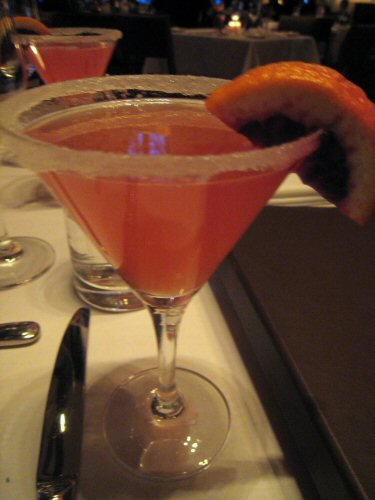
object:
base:
[102, 365, 233, 480]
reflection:
[58, 411, 66, 433]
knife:
[33, 305, 91, 499]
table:
[0, 160, 375, 499]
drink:
[12, 25, 122, 88]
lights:
[222, 12, 243, 35]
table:
[171, 27, 321, 90]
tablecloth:
[170, 25, 324, 81]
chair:
[144, 56, 169, 76]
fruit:
[206, 62, 375, 227]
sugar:
[39, 146, 174, 178]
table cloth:
[1, 158, 351, 500]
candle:
[228, 13, 243, 28]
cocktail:
[29, 99, 294, 297]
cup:
[2, 68, 333, 482]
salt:
[0, 134, 323, 185]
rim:
[2, 71, 327, 190]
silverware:
[32, 305, 91, 500]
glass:
[18, 26, 124, 86]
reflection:
[182, 433, 200, 454]